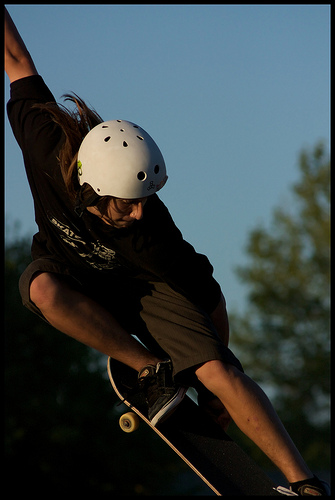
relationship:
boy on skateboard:
[22, 78, 179, 285] [114, 356, 264, 498]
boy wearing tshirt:
[22, 78, 179, 285] [12, 80, 155, 266]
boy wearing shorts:
[22, 78, 179, 285] [14, 241, 251, 372]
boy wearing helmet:
[22, 78, 179, 285] [72, 107, 171, 202]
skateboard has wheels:
[114, 356, 264, 498] [105, 406, 157, 445]